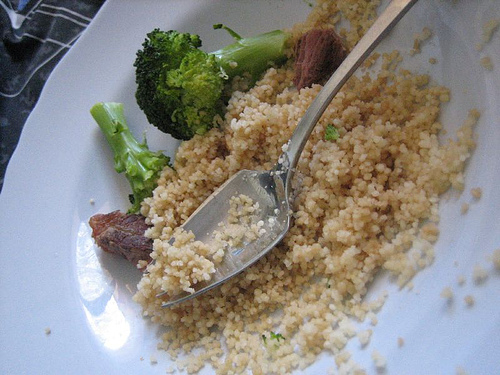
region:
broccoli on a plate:
[113, 20, 292, 120]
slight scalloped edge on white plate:
[16, 36, 82, 198]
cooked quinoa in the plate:
[311, 159, 430, 263]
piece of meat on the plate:
[83, 208, 160, 282]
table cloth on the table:
[5, 22, 41, 94]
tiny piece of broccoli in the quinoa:
[320, 122, 339, 144]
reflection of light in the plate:
[78, 232, 138, 352]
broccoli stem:
[95, 90, 140, 170]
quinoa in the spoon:
[156, 243, 211, 282]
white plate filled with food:
[14, 0, 495, 361]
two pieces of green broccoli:
[95, 19, 302, 191]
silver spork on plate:
[127, 18, 447, 318]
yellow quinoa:
[159, 103, 408, 328]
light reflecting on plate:
[68, 216, 129, 368]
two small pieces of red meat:
[92, 24, 368, 261]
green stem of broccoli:
[89, 97, 177, 203]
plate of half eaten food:
[35, 16, 492, 356]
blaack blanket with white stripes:
[10, 8, 72, 116]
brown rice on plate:
[151, 90, 403, 341]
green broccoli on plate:
[68, 47, 276, 189]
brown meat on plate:
[67, 184, 164, 278]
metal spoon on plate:
[145, 11, 389, 298]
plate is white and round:
[30, 14, 462, 321]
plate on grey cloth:
[14, 45, 495, 373]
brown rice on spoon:
[155, 150, 263, 335]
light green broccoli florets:
[154, 47, 216, 118]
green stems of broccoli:
[102, 95, 149, 169]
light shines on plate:
[57, 231, 164, 371]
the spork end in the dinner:
[147, 160, 297, 312]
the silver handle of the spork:
[278, 0, 413, 171]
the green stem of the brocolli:
[93, 96, 163, 191]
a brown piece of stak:
[85, 208, 165, 271]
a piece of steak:
[296, 25, 344, 85]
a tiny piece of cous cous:
[368, 312, 379, 328]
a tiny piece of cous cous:
[285, 298, 294, 310]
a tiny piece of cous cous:
[201, 337, 211, 345]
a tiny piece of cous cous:
[143, 350, 161, 361]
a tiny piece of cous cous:
[395, 336, 404, 348]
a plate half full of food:
[175, 71, 452, 307]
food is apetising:
[146, 69, 413, 235]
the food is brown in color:
[323, 144, 428, 272]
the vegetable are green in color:
[152, 23, 247, 121]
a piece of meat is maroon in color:
[86, 202, 149, 262]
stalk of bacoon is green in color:
[76, 97, 168, 197]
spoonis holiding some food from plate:
[160, 92, 380, 239]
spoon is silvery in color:
[156, 97, 323, 294]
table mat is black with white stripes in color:
[19, 5, 59, 67]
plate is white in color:
[21, 175, 87, 353]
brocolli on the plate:
[133, 5, 220, 132]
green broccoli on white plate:
[121, 13, 298, 149]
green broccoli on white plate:
[89, 94, 178, 206]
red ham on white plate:
[71, 197, 159, 267]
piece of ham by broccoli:
[131, 17, 352, 144]